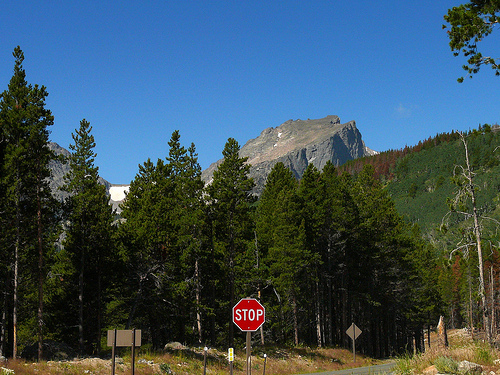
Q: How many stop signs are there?
A: One.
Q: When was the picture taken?
A: Daytime.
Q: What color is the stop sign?
A: Red and white.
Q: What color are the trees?
A: Green.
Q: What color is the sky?
A: Blue.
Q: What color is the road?
A: Gray.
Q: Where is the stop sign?
A: On the post.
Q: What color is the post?
A: Brown.